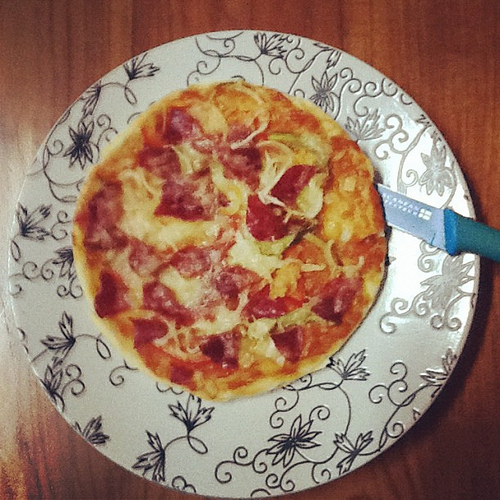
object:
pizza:
[70, 82, 388, 405]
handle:
[444, 207, 499, 261]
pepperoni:
[152, 179, 212, 220]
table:
[0, 1, 499, 500]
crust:
[229, 302, 373, 398]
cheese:
[128, 203, 153, 227]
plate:
[9, 32, 483, 500]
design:
[216, 347, 461, 498]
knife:
[375, 180, 499, 259]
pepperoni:
[128, 237, 171, 276]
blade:
[375, 181, 445, 254]